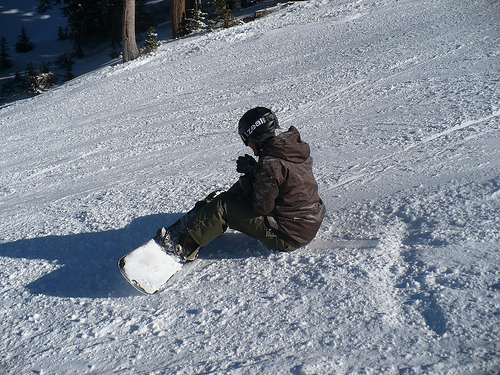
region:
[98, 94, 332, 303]
snow boarder sitting in snow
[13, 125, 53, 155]
white snow on hill side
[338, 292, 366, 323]
white snow on hill side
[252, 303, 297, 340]
white snow on hill side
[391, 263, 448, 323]
white snow on hill side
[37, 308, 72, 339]
white snow on hill side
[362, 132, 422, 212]
white snow on hill side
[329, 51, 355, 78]
white snow on hill side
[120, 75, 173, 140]
white snow on hill side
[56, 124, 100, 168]
white snow on hill side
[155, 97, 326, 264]
man is on snowboard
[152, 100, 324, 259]
man is sitting in snow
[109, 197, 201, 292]
snowboard is covered in snow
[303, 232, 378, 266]
track in snow from man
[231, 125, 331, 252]
man wearing a jacket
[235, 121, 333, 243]
mans jacket is brown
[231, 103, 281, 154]
man is wearing helmet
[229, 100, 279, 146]
mans helmet is black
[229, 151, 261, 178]
glove on right hand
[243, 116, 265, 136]
words on mans helmet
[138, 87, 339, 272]
a snowboarder on a hill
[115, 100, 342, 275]
snowboarder sits on the snow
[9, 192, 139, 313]
a shadow cast on the snow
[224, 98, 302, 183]
woman wears a helmet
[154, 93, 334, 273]
woman has brown coat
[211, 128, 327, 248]
brown coat with a hood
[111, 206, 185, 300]
a white snowboar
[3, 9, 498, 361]
a hill covered with snow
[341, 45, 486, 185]
marks of skis on the snow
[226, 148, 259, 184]
a black glove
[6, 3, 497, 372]
snowy suface of slope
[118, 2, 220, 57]
trees on side of slope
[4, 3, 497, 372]
marks on snow surface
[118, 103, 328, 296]
snowboarder sitting on ground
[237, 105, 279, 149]
black helmet on snowboarder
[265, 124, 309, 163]
hood on back of jacket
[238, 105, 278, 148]
strap on side of helmet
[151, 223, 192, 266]
boot on top of snowboard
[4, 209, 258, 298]
shadow on top of snow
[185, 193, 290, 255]
snow pants on legs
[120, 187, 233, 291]
white and black snow board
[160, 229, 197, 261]
black boot on snow board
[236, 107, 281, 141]
black and white helmet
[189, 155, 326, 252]
brown padded snow suit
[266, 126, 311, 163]
brown cotton sweatshirt hood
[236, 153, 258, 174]
black padded winter glove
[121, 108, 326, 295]
person sitting in snow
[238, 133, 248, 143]
black goggles on face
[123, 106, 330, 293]
person with feet on snow board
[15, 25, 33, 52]
green tree in snow